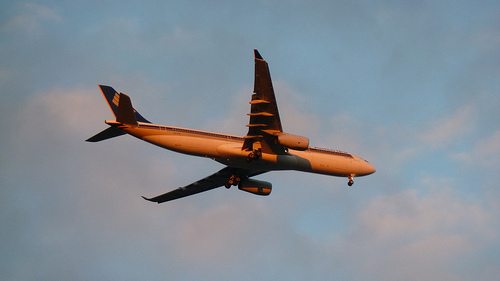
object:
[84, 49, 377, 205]
airplane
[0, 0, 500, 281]
sky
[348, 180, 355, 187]
wheel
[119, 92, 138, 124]
wing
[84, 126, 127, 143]
wing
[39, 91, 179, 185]
cloud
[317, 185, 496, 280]
cloud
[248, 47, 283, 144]
wing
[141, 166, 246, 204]
wing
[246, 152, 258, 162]
wheel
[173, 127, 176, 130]
window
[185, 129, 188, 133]
window